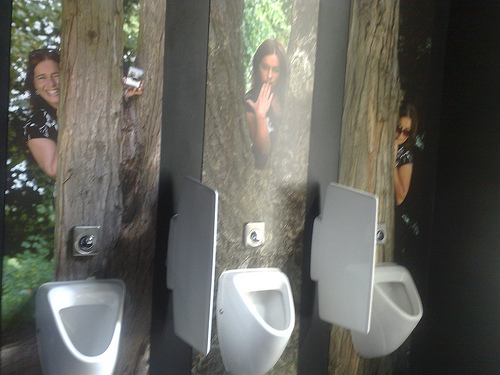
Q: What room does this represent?
A: It represents the bathroom.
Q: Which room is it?
A: It is a bathroom.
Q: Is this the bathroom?
A: Yes, it is the bathroom.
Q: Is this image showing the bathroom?
A: Yes, it is showing the bathroom.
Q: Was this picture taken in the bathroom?
A: Yes, it was taken in the bathroom.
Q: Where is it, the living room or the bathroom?
A: It is the bathroom.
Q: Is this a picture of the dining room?
A: No, the picture is showing the bathroom.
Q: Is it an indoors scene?
A: Yes, it is indoors.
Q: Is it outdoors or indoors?
A: It is indoors.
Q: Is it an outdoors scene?
A: No, it is indoors.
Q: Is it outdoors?
A: No, it is indoors.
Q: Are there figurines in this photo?
A: No, there are no figurines.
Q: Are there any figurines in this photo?
A: No, there are no figurines.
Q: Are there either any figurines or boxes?
A: No, there are no figurines or boxes.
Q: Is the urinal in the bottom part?
A: Yes, the urinal is in the bottom of the image.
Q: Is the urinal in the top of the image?
A: No, the urinal is in the bottom of the image.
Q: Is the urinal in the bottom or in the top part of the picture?
A: The urinal is in the bottom of the image.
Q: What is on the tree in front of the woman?
A: The urinal is on the tree.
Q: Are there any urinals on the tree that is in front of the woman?
A: Yes, there is a urinal on the tree.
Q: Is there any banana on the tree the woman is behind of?
A: No, there is a urinal on the tree.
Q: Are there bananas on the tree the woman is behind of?
A: No, there is a urinal on the tree.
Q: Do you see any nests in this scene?
A: No, there are no nests.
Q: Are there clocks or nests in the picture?
A: No, there are no nests or clocks.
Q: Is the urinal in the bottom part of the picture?
A: Yes, the urinal is in the bottom of the image.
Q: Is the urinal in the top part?
A: No, the urinal is in the bottom of the image.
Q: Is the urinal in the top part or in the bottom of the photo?
A: The urinal is in the bottom of the image.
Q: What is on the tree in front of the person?
A: The urinal is on the tree.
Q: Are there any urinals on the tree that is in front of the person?
A: Yes, there is a urinal on the tree.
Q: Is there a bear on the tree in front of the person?
A: No, there is a urinal on the tree.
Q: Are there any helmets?
A: No, there are no helmets.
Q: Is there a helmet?
A: No, there are no helmets.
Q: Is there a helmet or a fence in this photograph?
A: No, there are no helmets or fences.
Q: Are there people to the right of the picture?
A: Yes, there is a person to the right of the picture.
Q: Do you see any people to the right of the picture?
A: Yes, there is a person to the right of the picture.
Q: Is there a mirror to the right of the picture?
A: No, there is a person to the right of the picture.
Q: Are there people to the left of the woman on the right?
A: Yes, there is a person to the left of the woman.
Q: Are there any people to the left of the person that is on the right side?
A: Yes, there is a person to the left of the woman.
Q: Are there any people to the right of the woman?
A: No, the person is to the left of the woman.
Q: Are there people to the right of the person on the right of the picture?
A: No, the person is to the left of the woman.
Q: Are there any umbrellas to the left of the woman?
A: No, there is a person to the left of the woman.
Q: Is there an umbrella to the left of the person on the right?
A: No, there is a person to the left of the woman.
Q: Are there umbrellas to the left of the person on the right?
A: No, there is a person to the left of the woman.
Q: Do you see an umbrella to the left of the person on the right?
A: No, there is a person to the left of the woman.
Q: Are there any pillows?
A: No, there are no pillows.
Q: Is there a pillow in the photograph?
A: No, there are no pillows.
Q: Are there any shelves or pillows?
A: No, there are no pillows or shelves.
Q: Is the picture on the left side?
A: Yes, the picture is on the left of the image.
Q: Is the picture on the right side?
A: No, the picture is on the left of the image.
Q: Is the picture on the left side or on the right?
A: The picture is on the left of the image.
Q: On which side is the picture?
A: The picture is on the left of the image.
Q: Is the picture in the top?
A: Yes, the picture is in the top of the image.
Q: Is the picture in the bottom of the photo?
A: No, the picture is in the top of the image.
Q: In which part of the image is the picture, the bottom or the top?
A: The picture is in the top of the image.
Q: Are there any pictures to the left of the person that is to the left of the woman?
A: Yes, there is a picture to the left of the person.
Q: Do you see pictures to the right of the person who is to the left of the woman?
A: No, the picture is to the left of the person.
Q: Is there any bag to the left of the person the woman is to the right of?
A: No, there is a picture to the left of the person.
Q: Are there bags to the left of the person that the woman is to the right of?
A: No, there is a picture to the left of the person.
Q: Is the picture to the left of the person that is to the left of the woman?
A: Yes, the picture is to the left of the person.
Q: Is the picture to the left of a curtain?
A: No, the picture is to the left of the person.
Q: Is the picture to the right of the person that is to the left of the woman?
A: No, the picture is to the left of the person.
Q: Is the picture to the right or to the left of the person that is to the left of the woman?
A: The picture is to the left of the person.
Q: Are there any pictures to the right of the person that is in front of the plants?
A: Yes, there is a picture to the right of the person.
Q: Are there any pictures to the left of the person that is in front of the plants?
A: No, the picture is to the right of the person.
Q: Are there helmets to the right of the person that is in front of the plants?
A: No, there is a picture to the right of the person.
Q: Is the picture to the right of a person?
A: Yes, the picture is to the right of a person.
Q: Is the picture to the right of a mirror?
A: No, the picture is to the right of a person.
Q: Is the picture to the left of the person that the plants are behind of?
A: No, the picture is to the right of the person.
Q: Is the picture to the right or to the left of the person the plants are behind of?
A: The picture is to the right of the person.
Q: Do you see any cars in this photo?
A: No, there are no cars.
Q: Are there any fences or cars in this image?
A: No, there are no cars or fences.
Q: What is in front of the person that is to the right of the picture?
A: The tree is in front of the person.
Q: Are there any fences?
A: No, there are no fences.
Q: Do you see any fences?
A: No, there are no fences.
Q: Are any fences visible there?
A: No, there are no fences.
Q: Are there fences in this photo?
A: No, there are no fences.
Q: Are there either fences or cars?
A: No, there are no fences or cars.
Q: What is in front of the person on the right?
A: The tree is in front of the woman.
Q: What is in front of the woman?
A: The tree is in front of the woman.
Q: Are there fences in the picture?
A: No, there are no fences.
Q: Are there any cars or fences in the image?
A: No, there are no fences or cars.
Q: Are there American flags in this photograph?
A: No, there are no American flags.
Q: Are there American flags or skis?
A: No, there are no American flags or skis.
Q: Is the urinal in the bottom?
A: Yes, the urinal is in the bottom of the image.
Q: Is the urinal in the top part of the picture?
A: No, the urinal is in the bottom of the image.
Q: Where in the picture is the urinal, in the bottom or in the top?
A: The urinal is in the bottom of the image.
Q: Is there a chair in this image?
A: No, there are no chairs.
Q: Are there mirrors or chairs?
A: No, there are no chairs or mirrors.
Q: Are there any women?
A: Yes, there is a woman.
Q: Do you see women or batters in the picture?
A: Yes, there is a woman.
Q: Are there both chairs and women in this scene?
A: No, there is a woman but no chairs.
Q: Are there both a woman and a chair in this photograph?
A: No, there is a woman but no chairs.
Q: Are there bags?
A: No, there are no bags.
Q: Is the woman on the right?
A: Yes, the woman is on the right of the image.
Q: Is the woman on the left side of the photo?
A: No, the woman is on the right of the image.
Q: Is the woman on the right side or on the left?
A: The woman is on the right of the image.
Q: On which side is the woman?
A: The woman is on the right of the image.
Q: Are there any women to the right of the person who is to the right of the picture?
A: Yes, there is a woman to the right of the person.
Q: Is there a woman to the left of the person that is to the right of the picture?
A: No, the woman is to the right of the person.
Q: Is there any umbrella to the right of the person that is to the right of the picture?
A: No, there is a woman to the right of the person.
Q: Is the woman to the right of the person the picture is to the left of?
A: Yes, the woman is to the right of the person.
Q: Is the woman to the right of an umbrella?
A: No, the woman is to the right of the person.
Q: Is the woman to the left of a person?
A: No, the woman is to the right of a person.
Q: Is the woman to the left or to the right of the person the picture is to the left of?
A: The woman is to the right of the person.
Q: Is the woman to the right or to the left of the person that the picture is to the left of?
A: The woman is to the right of the person.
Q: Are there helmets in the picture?
A: No, there are no helmets.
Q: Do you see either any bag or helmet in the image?
A: No, there are no helmets or bags.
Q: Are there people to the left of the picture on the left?
A: Yes, there is a person to the left of the picture.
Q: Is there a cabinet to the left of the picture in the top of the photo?
A: No, there is a person to the left of the picture.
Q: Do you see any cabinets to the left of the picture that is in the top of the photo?
A: No, there is a person to the left of the picture.